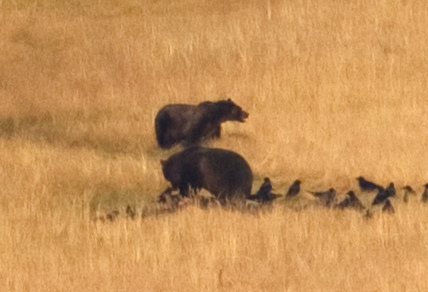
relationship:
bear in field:
[156, 97, 252, 148] [3, 0, 423, 288]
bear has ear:
[156, 97, 252, 148] [226, 95, 236, 103]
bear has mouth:
[156, 97, 252, 148] [239, 114, 249, 124]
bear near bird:
[156, 97, 252, 148] [284, 174, 303, 202]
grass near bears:
[1, 1, 428, 291] [155, 99, 254, 208]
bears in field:
[155, 99, 254, 208] [3, 0, 423, 288]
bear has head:
[156, 97, 252, 148] [225, 98, 252, 124]